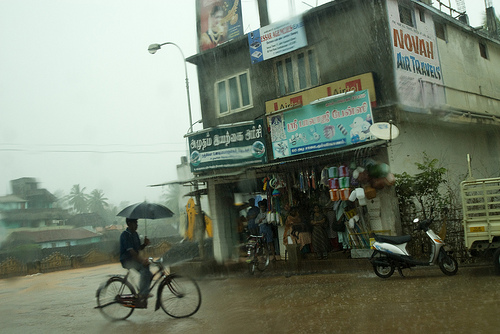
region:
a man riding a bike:
[85, 180, 195, 325]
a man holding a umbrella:
[105, 176, 176, 263]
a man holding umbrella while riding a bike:
[99, 188, 188, 305]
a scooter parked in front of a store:
[355, 208, 458, 290]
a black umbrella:
[114, 188, 172, 231]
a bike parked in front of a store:
[243, 218, 273, 276]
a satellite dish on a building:
[365, 103, 405, 162]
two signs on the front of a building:
[177, 91, 377, 193]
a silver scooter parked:
[360, 216, 457, 279]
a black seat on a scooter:
[368, 227, 421, 249]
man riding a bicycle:
[95, 211, 202, 321]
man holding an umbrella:
[115, 198, 174, 308]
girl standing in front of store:
[307, 203, 329, 261]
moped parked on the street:
[369, 218, 458, 282]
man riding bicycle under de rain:
[92, 199, 204, 320]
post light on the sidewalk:
[146, 39, 210, 262]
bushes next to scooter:
[394, 151, 463, 263]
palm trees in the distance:
[64, 179, 110, 215]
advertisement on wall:
[384, 0, 447, 110]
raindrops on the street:
[231, 269, 499, 331]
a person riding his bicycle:
[94, 216, 201, 325]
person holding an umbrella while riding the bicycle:
[96, 199, 201, 320]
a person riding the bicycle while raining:
[46, 157, 211, 325]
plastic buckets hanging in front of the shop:
[280, 102, 367, 271]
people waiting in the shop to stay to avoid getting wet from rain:
[269, 123, 334, 295]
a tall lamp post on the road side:
[112, 33, 200, 274]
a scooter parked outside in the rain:
[360, 205, 462, 287]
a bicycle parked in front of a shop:
[218, 168, 274, 282]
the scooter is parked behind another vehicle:
[366, 171, 498, 276]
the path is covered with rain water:
[20, 275, 497, 326]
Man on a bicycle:
[69, 172, 176, 332]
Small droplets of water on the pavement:
[452, 313, 468, 333]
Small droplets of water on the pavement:
[412, 269, 443, 309]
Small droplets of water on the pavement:
[445, 271, 466, 307]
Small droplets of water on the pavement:
[391, 287, 419, 327]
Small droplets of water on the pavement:
[327, 272, 355, 294]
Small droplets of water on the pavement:
[301, 285, 347, 331]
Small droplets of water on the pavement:
[256, 273, 303, 308]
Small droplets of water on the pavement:
[250, 302, 263, 317]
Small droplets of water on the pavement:
[25, 289, 93, 321]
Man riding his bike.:
[87, 195, 214, 325]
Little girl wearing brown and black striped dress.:
[309, 201, 336, 259]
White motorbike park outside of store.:
[365, 215, 465, 278]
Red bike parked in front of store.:
[241, 225, 273, 281]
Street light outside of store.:
[142, 39, 217, 259]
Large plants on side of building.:
[397, 155, 463, 250]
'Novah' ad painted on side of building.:
[388, 15, 450, 112]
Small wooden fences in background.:
[0, 238, 177, 277]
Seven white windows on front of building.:
[212, 43, 324, 117]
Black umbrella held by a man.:
[111, 198, 177, 248]